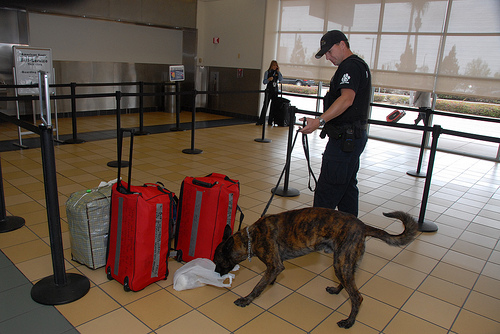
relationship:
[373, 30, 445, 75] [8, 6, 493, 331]
window of a building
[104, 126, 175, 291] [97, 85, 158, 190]
bag with handle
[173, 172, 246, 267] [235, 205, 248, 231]
bag with handle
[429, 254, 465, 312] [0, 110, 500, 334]
colored tiles on colored tiles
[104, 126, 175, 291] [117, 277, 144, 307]
bag with wheels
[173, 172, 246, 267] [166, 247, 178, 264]
bag with wheel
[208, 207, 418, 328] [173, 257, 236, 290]
dog sniffing bag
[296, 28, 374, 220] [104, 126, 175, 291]
cop pulling bag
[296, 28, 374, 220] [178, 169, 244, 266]
cop pulling suitcase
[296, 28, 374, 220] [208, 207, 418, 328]
cop brings dog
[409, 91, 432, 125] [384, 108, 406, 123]
woman dragging suitcase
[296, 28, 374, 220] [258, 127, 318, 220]
cop holding leash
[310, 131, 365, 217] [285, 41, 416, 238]
leg of man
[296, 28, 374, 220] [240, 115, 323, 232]
cop has leash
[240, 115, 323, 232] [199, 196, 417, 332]
leash on dog